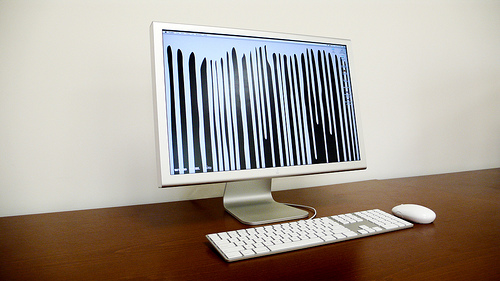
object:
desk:
[0, 167, 499, 280]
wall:
[1, 0, 152, 191]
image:
[161, 29, 361, 174]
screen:
[149, 20, 366, 187]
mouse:
[392, 203, 437, 224]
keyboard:
[205, 208, 414, 262]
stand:
[223, 178, 310, 225]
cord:
[282, 203, 317, 220]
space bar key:
[269, 237, 325, 251]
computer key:
[227, 237, 241, 243]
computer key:
[255, 233, 267, 238]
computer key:
[357, 229, 370, 234]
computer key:
[252, 246, 271, 254]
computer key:
[281, 229, 293, 234]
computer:
[149, 21, 437, 262]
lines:
[167, 45, 196, 175]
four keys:
[356, 224, 382, 235]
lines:
[211, 46, 239, 170]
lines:
[255, 45, 288, 169]